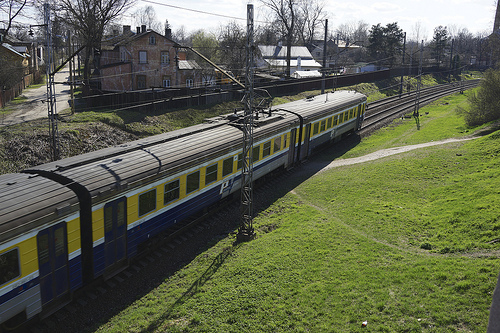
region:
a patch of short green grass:
[272, 173, 497, 322]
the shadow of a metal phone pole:
[141, 237, 248, 332]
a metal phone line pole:
[239, 41, 256, 241]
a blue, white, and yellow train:
[0, 81, 371, 331]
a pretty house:
[82, 25, 222, 97]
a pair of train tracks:
[364, 73, 481, 138]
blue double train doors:
[103, 197, 128, 274]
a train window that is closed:
[133, 189, 161, 216]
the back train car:
[288, 82, 373, 168]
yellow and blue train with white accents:
[66, 110, 301, 267]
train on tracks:
[300, 75, 475, 150]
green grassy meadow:
[280, 196, 485, 316]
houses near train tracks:
[90, 21, 376, 146]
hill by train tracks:
[0, 110, 115, 195]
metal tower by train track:
[236, 5, 256, 245]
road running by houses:
[6, 20, 96, 130]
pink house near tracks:
[110, 25, 221, 110]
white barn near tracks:
[251, 40, 321, 85]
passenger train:
[0, 87, 376, 327]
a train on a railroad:
[5, 83, 371, 328]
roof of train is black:
[0, 82, 370, 324]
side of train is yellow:
[8, 90, 373, 322]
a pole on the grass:
[219, 0, 279, 248]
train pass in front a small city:
[0, 15, 390, 322]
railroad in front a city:
[375, 67, 488, 129]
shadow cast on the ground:
[142, 244, 251, 316]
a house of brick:
[91, 15, 193, 92]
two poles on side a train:
[33, 0, 265, 237]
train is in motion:
[1, 82, 373, 329]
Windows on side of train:
[130, 102, 360, 219]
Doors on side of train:
[20, 191, 137, 306]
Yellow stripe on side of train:
[1, 95, 372, 291]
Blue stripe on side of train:
[0, 109, 367, 330]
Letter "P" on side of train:
[215, 176, 232, 198]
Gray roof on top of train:
[0, 69, 365, 244]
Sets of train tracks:
[355, 63, 481, 144]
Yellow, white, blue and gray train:
[2, 70, 382, 330]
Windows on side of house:
[135, 49, 192, 93]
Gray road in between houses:
[7, 49, 94, 130]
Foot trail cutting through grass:
[367, 243, 490, 263]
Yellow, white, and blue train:
[101, 163, 210, 241]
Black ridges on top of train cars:
[0, 179, 50, 214]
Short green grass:
[242, 245, 417, 327]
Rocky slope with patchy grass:
[57, 111, 109, 149]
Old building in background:
[97, 28, 184, 95]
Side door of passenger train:
[97, 194, 130, 284]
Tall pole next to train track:
[238, 3, 255, 244]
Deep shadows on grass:
[157, 242, 242, 327]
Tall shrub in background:
[459, 70, 499, 132]